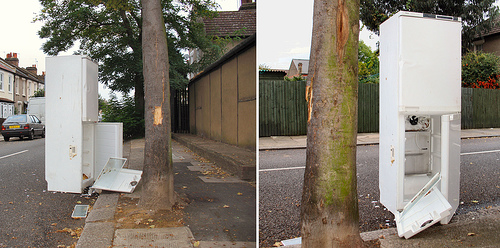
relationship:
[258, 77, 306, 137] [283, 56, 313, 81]
fencing covering house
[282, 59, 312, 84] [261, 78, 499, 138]
house and fence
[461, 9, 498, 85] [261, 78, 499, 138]
house and fence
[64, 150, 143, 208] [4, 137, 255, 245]
pieces are on ground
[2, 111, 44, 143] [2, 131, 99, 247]
car moving across road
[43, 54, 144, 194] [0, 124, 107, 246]
fridge on road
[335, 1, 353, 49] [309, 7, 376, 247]
hole on tree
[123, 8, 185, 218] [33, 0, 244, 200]
trunk on tree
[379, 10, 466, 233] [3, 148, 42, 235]
refrigerator in street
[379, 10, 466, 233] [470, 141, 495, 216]
refrigerator in street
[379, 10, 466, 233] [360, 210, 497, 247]
refrigerator sitting next to curb